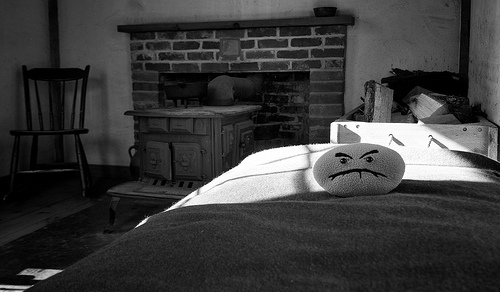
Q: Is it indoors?
A: Yes, it is indoors.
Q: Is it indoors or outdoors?
A: It is indoors.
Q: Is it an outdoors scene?
A: No, it is indoors.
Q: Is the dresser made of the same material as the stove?
A: Yes, both the dresser and the stove are made of wood.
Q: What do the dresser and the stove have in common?
A: The material, both the dresser and the stove are wooden.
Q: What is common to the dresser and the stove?
A: The material, both the dresser and the stove are wooden.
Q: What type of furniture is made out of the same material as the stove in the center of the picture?
A: The dresser is made of the same material as the stove.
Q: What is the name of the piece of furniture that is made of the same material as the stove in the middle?
A: The piece of furniture is a dresser.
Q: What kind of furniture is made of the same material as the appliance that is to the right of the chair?
A: The dresser is made of the same material as the stove.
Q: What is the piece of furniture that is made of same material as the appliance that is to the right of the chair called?
A: The piece of furniture is a dresser.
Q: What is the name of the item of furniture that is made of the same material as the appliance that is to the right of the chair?
A: The piece of furniture is a dresser.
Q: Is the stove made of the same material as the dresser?
A: Yes, both the stove and the dresser are made of wood.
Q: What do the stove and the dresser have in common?
A: The material, both the stove and the dresser are wooden.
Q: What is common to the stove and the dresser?
A: The material, both the stove and the dresser are wooden.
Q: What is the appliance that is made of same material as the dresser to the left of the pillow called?
A: The appliance is a stove.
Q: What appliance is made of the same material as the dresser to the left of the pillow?
A: The stove is made of the same material as the dresser.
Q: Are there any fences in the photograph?
A: No, there are no fences.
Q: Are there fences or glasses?
A: No, there are no fences or glasses.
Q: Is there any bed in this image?
A: Yes, there is a bed.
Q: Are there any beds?
A: Yes, there is a bed.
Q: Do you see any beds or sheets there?
A: Yes, there is a bed.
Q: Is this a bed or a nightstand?
A: This is a bed.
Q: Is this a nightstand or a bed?
A: This is a bed.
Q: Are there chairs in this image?
A: Yes, there is a chair.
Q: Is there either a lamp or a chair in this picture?
A: Yes, there is a chair.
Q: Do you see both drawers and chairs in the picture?
A: No, there is a chair but no drawers.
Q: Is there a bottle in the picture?
A: No, there are no bottles.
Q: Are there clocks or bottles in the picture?
A: No, there are no bottles or clocks.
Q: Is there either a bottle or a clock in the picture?
A: No, there are no bottles or clocks.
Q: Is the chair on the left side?
A: Yes, the chair is on the left of the image.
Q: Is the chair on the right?
A: No, the chair is on the left of the image.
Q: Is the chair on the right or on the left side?
A: The chair is on the left of the image.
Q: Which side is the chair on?
A: The chair is on the left of the image.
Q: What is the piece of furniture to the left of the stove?
A: The piece of furniture is a chair.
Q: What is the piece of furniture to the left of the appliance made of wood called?
A: The piece of furniture is a chair.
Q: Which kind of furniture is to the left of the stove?
A: The piece of furniture is a chair.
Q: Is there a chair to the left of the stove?
A: Yes, there is a chair to the left of the stove.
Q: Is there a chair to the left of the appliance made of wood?
A: Yes, there is a chair to the left of the stove.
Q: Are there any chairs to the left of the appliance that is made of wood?
A: Yes, there is a chair to the left of the stove.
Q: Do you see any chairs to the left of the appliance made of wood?
A: Yes, there is a chair to the left of the stove.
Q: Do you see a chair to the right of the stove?
A: No, the chair is to the left of the stove.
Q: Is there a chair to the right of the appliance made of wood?
A: No, the chair is to the left of the stove.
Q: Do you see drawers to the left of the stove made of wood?
A: No, there is a chair to the left of the stove.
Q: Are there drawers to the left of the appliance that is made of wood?
A: No, there is a chair to the left of the stove.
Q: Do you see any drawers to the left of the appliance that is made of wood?
A: No, there is a chair to the left of the stove.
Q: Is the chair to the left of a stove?
A: Yes, the chair is to the left of a stove.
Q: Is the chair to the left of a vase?
A: No, the chair is to the left of a stove.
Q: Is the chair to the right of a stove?
A: No, the chair is to the left of a stove.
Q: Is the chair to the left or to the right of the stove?
A: The chair is to the left of the stove.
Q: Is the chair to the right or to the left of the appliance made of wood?
A: The chair is to the left of the stove.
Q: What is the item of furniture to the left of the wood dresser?
A: The piece of furniture is a chair.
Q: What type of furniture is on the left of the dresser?
A: The piece of furniture is a chair.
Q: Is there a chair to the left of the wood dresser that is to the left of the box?
A: Yes, there is a chair to the left of the dresser.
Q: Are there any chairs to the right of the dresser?
A: No, the chair is to the left of the dresser.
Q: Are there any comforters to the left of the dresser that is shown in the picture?
A: No, there is a chair to the left of the dresser.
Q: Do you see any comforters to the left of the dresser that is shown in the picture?
A: No, there is a chair to the left of the dresser.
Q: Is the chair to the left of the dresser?
A: Yes, the chair is to the left of the dresser.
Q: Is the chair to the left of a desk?
A: No, the chair is to the left of the dresser.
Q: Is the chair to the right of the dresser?
A: No, the chair is to the left of the dresser.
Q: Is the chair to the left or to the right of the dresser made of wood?
A: The chair is to the left of the dresser.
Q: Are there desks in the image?
A: No, there are no desks.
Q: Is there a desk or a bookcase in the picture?
A: No, there are no desks or bookcases.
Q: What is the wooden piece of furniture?
A: The piece of furniture is a dresser.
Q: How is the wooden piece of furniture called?
A: The piece of furniture is a dresser.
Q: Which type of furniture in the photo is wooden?
A: The furniture is a dresser.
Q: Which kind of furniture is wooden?
A: The furniture is a dresser.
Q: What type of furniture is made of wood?
A: The furniture is a dresser.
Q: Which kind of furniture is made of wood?
A: The furniture is a dresser.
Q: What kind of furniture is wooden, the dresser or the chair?
A: The dresser is wooden.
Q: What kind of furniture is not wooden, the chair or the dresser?
A: The chair is not wooden.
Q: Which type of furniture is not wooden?
A: The furniture is a chair.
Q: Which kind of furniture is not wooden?
A: The furniture is a chair.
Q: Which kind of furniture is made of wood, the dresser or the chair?
A: The dresser is made of wood.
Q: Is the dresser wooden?
A: Yes, the dresser is wooden.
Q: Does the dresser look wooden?
A: Yes, the dresser is wooden.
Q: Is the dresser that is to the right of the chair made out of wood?
A: Yes, the dresser is made of wood.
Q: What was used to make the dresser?
A: The dresser is made of wood.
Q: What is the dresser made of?
A: The dresser is made of wood.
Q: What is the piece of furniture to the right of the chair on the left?
A: The piece of furniture is a dresser.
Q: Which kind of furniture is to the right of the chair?
A: The piece of furniture is a dresser.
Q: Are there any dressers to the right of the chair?
A: Yes, there is a dresser to the right of the chair.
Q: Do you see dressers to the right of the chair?
A: Yes, there is a dresser to the right of the chair.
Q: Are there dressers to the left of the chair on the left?
A: No, the dresser is to the right of the chair.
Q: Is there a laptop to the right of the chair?
A: No, there is a dresser to the right of the chair.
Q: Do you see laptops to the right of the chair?
A: No, there is a dresser to the right of the chair.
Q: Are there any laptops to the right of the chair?
A: No, there is a dresser to the right of the chair.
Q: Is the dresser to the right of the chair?
A: Yes, the dresser is to the right of the chair.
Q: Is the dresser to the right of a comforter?
A: No, the dresser is to the right of the chair.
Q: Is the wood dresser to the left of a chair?
A: No, the dresser is to the right of a chair.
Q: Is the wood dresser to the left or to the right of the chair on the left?
A: The dresser is to the right of the chair.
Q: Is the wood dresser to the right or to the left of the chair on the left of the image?
A: The dresser is to the right of the chair.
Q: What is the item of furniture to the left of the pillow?
A: The piece of furniture is a dresser.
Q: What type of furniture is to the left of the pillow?
A: The piece of furniture is a dresser.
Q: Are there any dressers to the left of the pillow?
A: Yes, there is a dresser to the left of the pillow.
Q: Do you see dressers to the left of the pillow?
A: Yes, there is a dresser to the left of the pillow.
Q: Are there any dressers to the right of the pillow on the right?
A: No, the dresser is to the left of the pillow.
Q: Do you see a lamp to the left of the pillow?
A: No, there is a dresser to the left of the pillow.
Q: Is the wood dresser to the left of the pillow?
A: Yes, the dresser is to the left of the pillow.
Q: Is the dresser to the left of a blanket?
A: No, the dresser is to the left of the pillow.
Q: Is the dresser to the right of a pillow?
A: No, the dresser is to the left of a pillow.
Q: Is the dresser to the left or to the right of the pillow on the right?
A: The dresser is to the left of the pillow.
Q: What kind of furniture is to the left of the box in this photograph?
A: The piece of furniture is a dresser.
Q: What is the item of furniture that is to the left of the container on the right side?
A: The piece of furniture is a dresser.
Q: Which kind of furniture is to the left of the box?
A: The piece of furniture is a dresser.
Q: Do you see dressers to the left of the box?
A: Yes, there is a dresser to the left of the box.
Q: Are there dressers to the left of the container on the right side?
A: Yes, there is a dresser to the left of the box.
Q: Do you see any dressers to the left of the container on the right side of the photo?
A: Yes, there is a dresser to the left of the box.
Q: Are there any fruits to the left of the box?
A: No, there is a dresser to the left of the box.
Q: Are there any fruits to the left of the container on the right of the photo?
A: No, there is a dresser to the left of the box.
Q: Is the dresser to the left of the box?
A: Yes, the dresser is to the left of the box.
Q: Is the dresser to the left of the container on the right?
A: Yes, the dresser is to the left of the box.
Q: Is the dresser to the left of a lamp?
A: No, the dresser is to the left of the box.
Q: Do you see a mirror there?
A: No, there are no mirrors.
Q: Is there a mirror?
A: No, there are no mirrors.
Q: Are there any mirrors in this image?
A: No, there are no mirrors.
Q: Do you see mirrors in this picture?
A: No, there are no mirrors.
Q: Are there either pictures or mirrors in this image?
A: No, there are no mirrors or pictures.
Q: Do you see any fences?
A: No, there are no fences.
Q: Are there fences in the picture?
A: No, there are no fences.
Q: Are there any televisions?
A: No, there are no televisions.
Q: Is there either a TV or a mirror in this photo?
A: No, there are no televisions or mirrors.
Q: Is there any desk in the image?
A: No, there are no desks.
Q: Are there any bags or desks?
A: No, there are no desks or bags.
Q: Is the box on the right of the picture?
A: Yes, the box is on the right of the image.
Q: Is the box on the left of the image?
A: No, the box is on the right of the image.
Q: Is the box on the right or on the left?
A: The box is on the right of the image.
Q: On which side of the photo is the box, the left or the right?
A: The box is on the right of the image.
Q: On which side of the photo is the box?
A: The box is on the right of the image.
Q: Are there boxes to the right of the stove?
A: Yes, there is a box to the right of the stove.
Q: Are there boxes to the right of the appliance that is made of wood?
A: Yes, there is a box to the right of the stove.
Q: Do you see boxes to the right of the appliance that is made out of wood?
A: Yes, there is a box to the right of the stove.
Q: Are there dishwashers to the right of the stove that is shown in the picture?
A: No, there is a box to the right of the stove.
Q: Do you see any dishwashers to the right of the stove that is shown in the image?
A: No, there is a box to the right of the stove.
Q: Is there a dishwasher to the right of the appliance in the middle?
A: No, there is a box to the right of the stove.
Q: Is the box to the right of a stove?
A: Yes, the box is to the right of a stove.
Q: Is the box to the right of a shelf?
A: No, the box is to the right of a stove.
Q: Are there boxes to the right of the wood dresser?
A: Yes, there is a box to the right of the dresser.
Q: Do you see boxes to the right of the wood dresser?
A: Yes, there is a box to the right of the dresser.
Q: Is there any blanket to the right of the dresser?
A: No, there is a box to the right of the dresser.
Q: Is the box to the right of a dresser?
A: Yes, the box is to the right of a dresser.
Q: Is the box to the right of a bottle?
A: No, the box is to the right of a dresser.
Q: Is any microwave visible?
A: No, there are no microwaves.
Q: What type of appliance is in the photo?
A: The appliance is a stove.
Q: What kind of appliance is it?
A: The appliance is a stove.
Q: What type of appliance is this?
A: That is a stove.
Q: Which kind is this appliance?
A: That is a stove.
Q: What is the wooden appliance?
A: The appliance is a stove.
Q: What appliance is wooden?
A: The appliance is a stove.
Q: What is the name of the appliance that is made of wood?
A: The appliance is a stove.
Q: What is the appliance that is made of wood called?
A: The appliance is a stove.